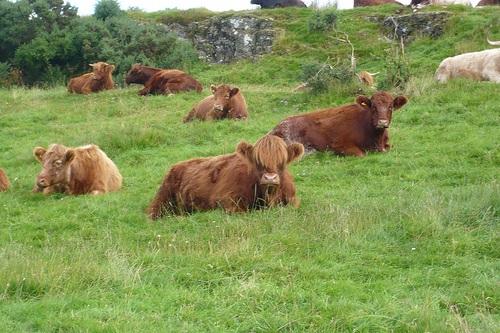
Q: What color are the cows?
A: Brown.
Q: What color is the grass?
A: Green.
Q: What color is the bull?
A: White.